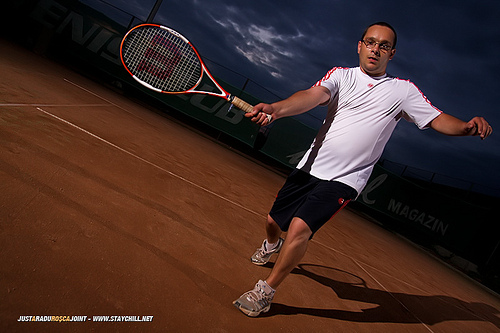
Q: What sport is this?
A: Tennis.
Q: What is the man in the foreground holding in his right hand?
A: Tennis racket.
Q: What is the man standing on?
A: Tennis court.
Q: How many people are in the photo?
A: One.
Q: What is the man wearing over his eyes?
A: Eyeglasses.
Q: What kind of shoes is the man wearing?
A: Sneakers.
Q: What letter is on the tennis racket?
A: W.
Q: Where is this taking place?
A: At the tennis court.